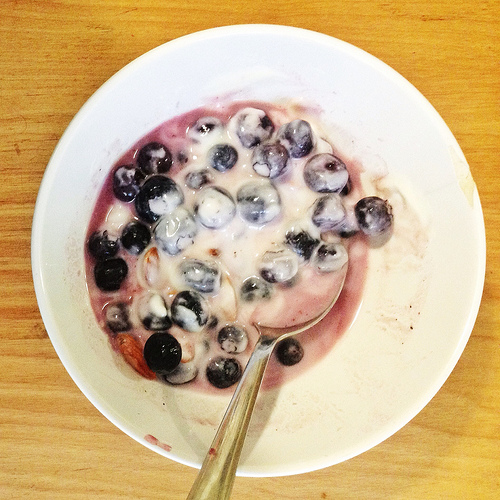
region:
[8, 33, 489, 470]
A plate full of food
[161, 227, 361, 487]
A silver spoon scoops food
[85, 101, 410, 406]
Black balls are in the plate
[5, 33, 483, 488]
The plate is on a wooden table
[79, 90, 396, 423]
Red liquid is in the plate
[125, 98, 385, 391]
White liquid is in the plate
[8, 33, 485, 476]
The white plate is on a light brown table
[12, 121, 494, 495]
The table is light brown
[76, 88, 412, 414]
The plate is half full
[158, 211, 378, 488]
The spoon is scooping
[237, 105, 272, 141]
one blueberry in cream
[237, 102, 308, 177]
three blueberries in cream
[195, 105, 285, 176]
four blueberries in cream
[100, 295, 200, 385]
five blueberries in cream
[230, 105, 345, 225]
six blueberries in cream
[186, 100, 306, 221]
eight blueberries in cream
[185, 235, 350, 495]
the spoon in a bowl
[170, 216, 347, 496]
the spoon in a bowl of blueberries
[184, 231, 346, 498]
the spoon in a bowl of blueberries and cream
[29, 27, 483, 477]
a bowl of blueberries and creme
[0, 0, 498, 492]
a white dish on a table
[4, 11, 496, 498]
table is made of wood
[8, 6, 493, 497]
wood table is color brown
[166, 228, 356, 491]
a spoon on a dish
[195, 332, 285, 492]
handle of the spoon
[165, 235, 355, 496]
spoon is color silver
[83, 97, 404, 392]
blueberries on a white dish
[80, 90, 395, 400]
blueberries with white cream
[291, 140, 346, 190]
a blueberry with cream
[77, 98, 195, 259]
cream is purple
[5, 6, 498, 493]
A light wooden table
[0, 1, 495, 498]
A bowl of food on a light colored wooden table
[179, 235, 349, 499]
A silver metal spoon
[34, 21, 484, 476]
A small white bowl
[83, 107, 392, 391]
a bunch of blueberry's and cream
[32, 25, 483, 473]
A white bowl filled with fruit and cream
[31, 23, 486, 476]
A white bowl filled with blueberries and cream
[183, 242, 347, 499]
A spoon dipped in some fruit and cream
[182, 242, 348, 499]
A spoon sitting in some blueberries and cream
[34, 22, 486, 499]
A white bowl with a spoon dipped in some blueberries and cream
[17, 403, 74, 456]
Maple Wooden serving table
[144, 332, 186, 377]
Black berry in desert bowl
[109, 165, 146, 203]
Berry in desert serving bown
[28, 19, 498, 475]
Delicious berry desert in bowl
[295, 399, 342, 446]
White bowl for serving desert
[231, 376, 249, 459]
Part of serving spoon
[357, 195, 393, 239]
Delicious berry in serving bowl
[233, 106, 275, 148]
Delicious berry in serving bowl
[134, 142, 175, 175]
Delicious berry in serving bowl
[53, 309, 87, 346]
Part of white serving bowl